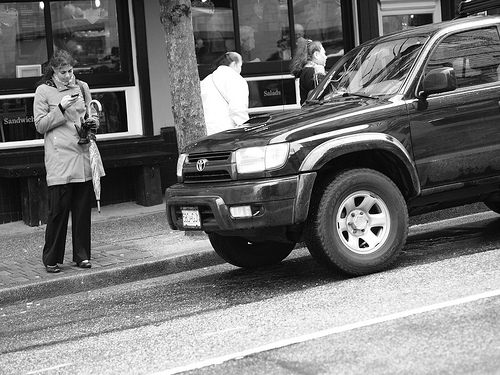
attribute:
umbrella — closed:
[82, 97, 106, 217]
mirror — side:
[417, 63, 457, 98]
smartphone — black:
[70, 89, 80, 104]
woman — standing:
[24, 44, 112, 276]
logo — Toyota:
[185, 154, 220, 179]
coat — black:
[293, 62, 329, 92]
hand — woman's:
[58, 87, 80, 113]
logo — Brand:
[186, 161, 216, 171]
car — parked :
[161, 7, 499, 271]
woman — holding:
[44, 61, 106, 278]